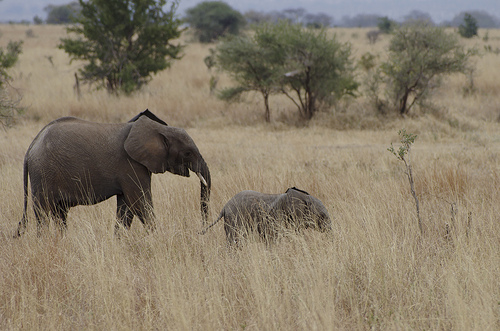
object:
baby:
[198, 186, 333, 245]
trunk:
[196, 170, 211, 225]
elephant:
[13, 108, 212, 240]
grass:
[0, 126, 499, 330]